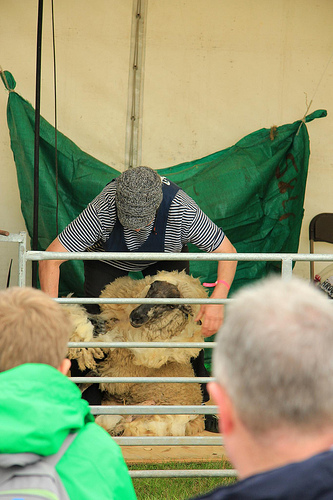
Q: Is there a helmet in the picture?
A: No, there are no helmets.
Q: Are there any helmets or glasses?
A: No, there are no helmets or glasses.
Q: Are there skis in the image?
A: No, there are no skis.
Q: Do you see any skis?
A: No, there are no skis.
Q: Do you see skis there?
A: No, there are no skis.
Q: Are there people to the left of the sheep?
A: Yes, there are people to the left of the sheep.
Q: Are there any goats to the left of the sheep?
A: No, there are people to the left of the sheep.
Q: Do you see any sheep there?
A: Yes, there is a sheep.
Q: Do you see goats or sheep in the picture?
A: Yes, there is a sheep.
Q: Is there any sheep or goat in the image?
A: Yes, there is a sheep.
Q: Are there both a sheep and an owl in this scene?
A: No, there is a sheep but no owls.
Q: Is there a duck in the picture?
A: No, there are no ducks.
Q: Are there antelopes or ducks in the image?
A: No, there are no ducks or antelopes.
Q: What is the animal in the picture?
A: The animal is a sheep.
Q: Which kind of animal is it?
A: The animal is a sheep.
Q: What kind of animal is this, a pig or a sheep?
A: That is a sheep.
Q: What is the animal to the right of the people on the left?
A: The animal is a sheep.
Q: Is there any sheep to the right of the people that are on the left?
A: Yes, there is a sheep to the right of the people.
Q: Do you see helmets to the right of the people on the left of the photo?
A: No, there is a sheep to the right of the people.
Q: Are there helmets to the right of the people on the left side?
A: No, there is a sheep to the right of the people.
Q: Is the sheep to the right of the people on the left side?
A: Yes, the sheep is to the right of the people.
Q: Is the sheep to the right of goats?
A: No, the sheep is to the right of the people.